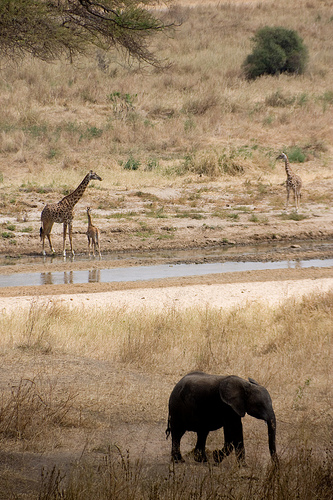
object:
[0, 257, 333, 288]
ripples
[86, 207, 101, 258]
young giraffe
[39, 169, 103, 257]
large giraffe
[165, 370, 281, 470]
elephant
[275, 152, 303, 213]
giraffe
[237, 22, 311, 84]
bush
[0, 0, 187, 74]
tree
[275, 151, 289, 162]
head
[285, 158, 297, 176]
neck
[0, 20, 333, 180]
vegetation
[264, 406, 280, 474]
trunk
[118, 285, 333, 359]
grass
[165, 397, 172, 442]
tail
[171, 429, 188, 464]
back legs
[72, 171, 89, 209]
neck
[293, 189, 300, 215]
front legs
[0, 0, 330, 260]
field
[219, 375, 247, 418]
ear